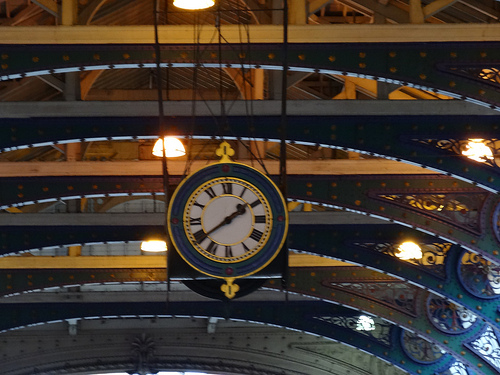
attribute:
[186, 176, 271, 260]
face — white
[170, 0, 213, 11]
light — on, domed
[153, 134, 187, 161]
light — on, domed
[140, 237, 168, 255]
light — on, domed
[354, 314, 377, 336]
light — on, domed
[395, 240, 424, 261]
light — on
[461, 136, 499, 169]
light — on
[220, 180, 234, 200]
number — black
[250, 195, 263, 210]
number — black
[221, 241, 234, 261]
number — black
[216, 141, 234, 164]
decoration — ornate, gold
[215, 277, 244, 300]
decoration — ornate, gold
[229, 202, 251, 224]
hand — black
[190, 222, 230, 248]
hand — black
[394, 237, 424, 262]
light — hung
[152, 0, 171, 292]
supports — black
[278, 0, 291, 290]
supports — metal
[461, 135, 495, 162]
light — hung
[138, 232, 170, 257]
ceiling light — on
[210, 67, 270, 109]
frame — wood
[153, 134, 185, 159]
light — hung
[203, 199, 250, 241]
hand — black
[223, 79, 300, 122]
frame — brown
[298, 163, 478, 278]
ceiling — decorative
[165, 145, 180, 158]
light bulb — yellow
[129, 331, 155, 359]
artwork — ornate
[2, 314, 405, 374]
beam — iron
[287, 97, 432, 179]
frame — mettalic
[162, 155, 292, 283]
clock — ornate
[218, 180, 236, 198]
numeral 12 — roman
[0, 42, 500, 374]
supports — arched, decorative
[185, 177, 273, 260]
clockface — white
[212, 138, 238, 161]
ornamentation — gold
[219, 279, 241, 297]
ornamentation — gold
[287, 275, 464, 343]
ceiling supports — steel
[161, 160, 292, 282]
frame — yellow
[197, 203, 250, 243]
handles — black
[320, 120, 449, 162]
frame — blue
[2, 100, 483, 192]
support — arched, decorative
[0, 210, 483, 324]
support — arched, decorative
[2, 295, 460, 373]
support — arched, decorative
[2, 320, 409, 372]
support — arched, decorative